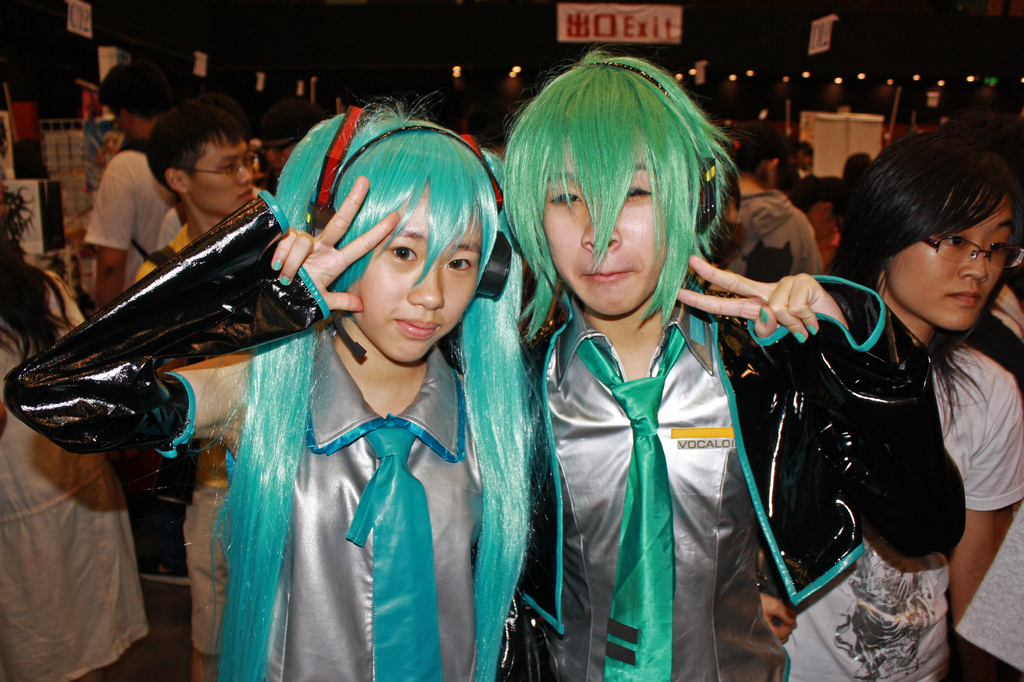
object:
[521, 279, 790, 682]
shirt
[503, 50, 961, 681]
guy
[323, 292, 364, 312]
thumb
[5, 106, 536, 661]
person